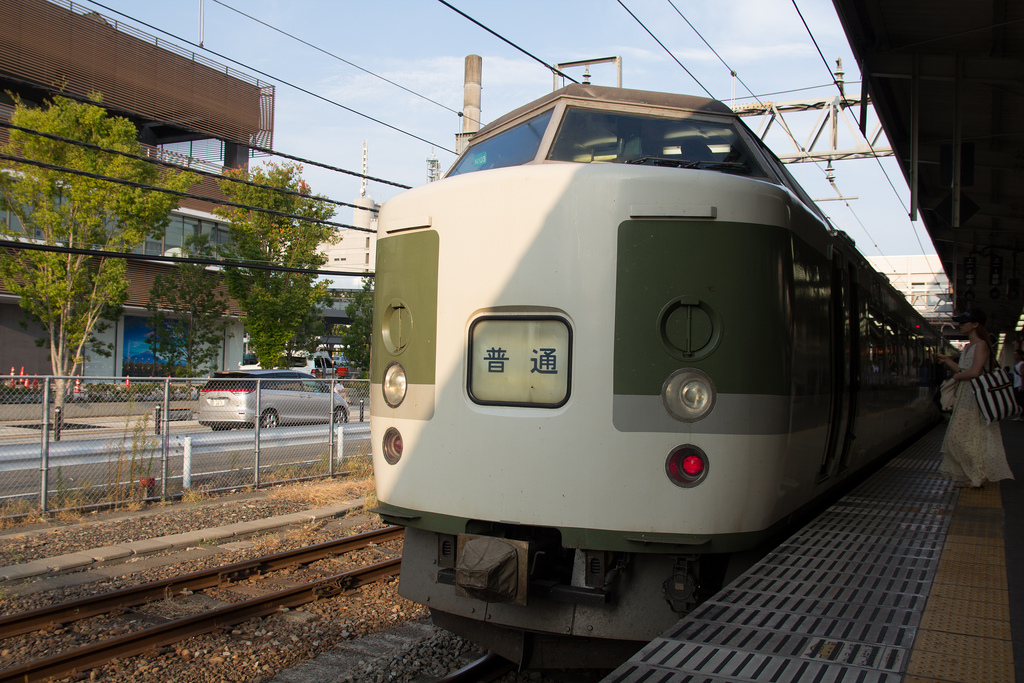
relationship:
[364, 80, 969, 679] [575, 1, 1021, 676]
train at station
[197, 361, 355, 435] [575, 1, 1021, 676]
van passing station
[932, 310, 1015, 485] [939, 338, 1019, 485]
woman in dress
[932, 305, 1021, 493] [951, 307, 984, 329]
woman in baseball cap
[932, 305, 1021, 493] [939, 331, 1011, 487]
woman in dress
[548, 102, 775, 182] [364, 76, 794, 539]
window on front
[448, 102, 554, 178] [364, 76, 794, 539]
window on front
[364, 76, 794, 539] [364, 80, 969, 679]
front of train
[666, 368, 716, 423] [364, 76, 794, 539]
light on front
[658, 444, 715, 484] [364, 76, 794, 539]
light on front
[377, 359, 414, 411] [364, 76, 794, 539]
light on front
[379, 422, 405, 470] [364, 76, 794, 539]
light on front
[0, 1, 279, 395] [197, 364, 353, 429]
building beside van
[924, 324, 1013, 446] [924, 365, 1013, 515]
woman with dress